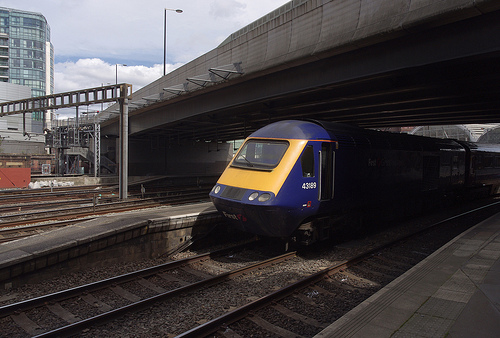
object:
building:
[0, 7, 59, 157]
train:
[205, 116, 497, 268]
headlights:
[211, 186, 216, 191]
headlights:
[209, 185, 219, 195]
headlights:
[245, 189, 259, 202]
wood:
[105, 280, 147, 307]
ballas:
[47, 196, 497, 336]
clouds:
[1, 1, 290, 59]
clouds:
[50, 53, 181, 121]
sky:
[2, 1, 288, 131]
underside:
[119, 49, 498, 146]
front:
[205, 127, 306, 225]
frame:
[5, 83, 135, 209]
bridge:
[58, 1, 495, 167]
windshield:
[233, 136, 288, 171]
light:
[175, 10, 183, 13]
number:
[299, 179, 317, 193]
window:
[299, 147, 315, 179]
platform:
[394, 255, 495, 333]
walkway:
[1, 199, 230, 267]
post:
[114, 81, 136, 198]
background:
[287, 172, 325, 202]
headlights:
[257, 191, 269, 205]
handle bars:
[318, 149, 323, 204]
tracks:
[18, 236, 185, 336]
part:
[213, 196, 260, 226]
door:
[317, 134, 338, 214]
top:
[245, 106, 334, 172]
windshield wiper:
[235, 152, 255, 169]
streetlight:
[143, 3, 190, 72]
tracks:
[4, 62, 150, 199]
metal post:
[88, 190, 100, 214]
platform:
[375, 217, 488, 335]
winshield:
[435, 151, 455, 181]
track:
[73, 210, 276, 327]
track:
[115, 256, 201, 313]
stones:
[140, 243, 240, 304]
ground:
[99, 270, 269, 332]